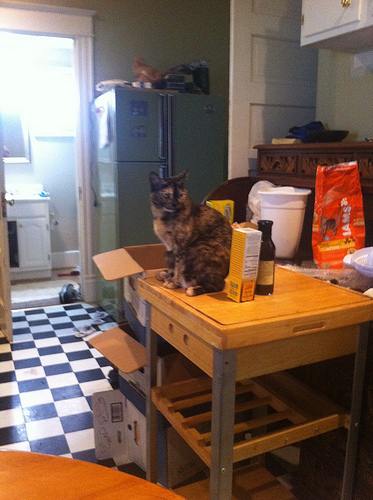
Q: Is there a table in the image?
A: Yes, there is a table.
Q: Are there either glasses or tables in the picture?
A: Yes, there is a table.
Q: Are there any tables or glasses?
A: Yes, there is a table.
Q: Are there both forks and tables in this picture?
A: No, there is a table but no forks.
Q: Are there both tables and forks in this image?
A: No, there is a table but no forks.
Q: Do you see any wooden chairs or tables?
A: Yes, there is a wood table.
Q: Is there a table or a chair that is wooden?
A: Yes, the table is wooden.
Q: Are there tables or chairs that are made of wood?
A: Yes, the table is made of wood.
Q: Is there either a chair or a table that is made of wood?
A: Yes, the table is made of wood.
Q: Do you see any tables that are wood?
A: Yes, there is a wood table.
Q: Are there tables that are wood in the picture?
A: Yes, there is a wood table.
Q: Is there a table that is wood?
A: Yes, there is a wood table.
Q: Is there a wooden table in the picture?
A: Yes, there is a wood table.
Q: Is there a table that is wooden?
A: Yes, there is a table that is wooden.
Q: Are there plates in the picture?
A: No, there are no plates.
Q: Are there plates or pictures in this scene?
A: No, there are no plates or pictures.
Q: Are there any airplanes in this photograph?
A: No, there are no airplanes.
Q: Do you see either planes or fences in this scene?
A: No, there are no planes or fences.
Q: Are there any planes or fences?
A: No, there are no planes or fences.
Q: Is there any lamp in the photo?
A: No, there are no lamps.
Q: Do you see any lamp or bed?
A: No, there are no lamps or beds.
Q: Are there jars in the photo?
A: No, there are no jars.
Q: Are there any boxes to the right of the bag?
A: No, the box is to the left of the bag.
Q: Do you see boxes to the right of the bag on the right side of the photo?
A: No, the box is to the left of the bag.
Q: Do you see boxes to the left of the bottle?
A: Yes, there is a box to the left of the bottle.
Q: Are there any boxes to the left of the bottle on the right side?
A: Yes, there is a box to the left of the bottle.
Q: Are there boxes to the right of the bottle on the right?
A: No, the box is to the left of the bottle.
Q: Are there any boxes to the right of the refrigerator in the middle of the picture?
A: Yes, there is a box to the right of the freezer.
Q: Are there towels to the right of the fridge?
A: No, there is a box to the right of the fridge.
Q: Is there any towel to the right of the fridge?
A: No, there is a box to the right of the fridge.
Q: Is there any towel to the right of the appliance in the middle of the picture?
A: No, there is a box to the right of the fridge.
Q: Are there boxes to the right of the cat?
A: Yes, there is a box to the right of the cat.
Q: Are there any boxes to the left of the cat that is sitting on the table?
A: No, the box is to the right of the cat.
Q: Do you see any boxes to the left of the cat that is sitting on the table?
A: No, the box is to the right of the cat.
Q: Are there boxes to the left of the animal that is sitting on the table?
A: No, the box is to the right of the cat.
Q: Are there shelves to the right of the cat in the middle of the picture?
A: No, there is a box to the right of the cat.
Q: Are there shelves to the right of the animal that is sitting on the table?
A: No, there is a box to the right of the cat.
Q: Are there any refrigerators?
A: Yes, there is a refrigerator.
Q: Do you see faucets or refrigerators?
A: Yes, there is a refrigerator.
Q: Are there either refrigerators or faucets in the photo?
A: Yes, there is a refrigerator.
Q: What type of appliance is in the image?
A: The appliance is a refrigerator.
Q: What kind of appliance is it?
A: The appliance is a refrigerator.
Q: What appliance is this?
A: This is a refrigerator.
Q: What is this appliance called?
A: This is a refrigerator.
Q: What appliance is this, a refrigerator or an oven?
A: This is a refrigerator.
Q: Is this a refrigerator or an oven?
A: This is a refrigerator.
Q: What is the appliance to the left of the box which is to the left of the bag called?
A: The appliance is a refrigerator.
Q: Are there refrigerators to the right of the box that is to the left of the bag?
A: No, the refrigerator is to the left of the box.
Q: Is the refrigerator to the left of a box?
A: Yes, the refrigerator is to the left of a box.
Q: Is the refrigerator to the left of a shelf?
A: No, the refrigerator is to the left of a box.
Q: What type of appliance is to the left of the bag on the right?
A: The appliance is a refrigerator.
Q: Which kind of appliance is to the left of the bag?
A: The appliance is a refrigerator.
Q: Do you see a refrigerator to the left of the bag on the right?
A: Yes, there is a refrigerator to the left of the bag.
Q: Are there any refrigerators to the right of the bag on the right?
A: No, the refrigerator is to the left of the bag.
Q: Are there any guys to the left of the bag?
A: No, there is a refrigerator to the left of the bag.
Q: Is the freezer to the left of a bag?
A: Yes, the freezer is to the left of a bag.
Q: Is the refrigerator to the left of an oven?
A: No, the refrigerator is to the left of a bag.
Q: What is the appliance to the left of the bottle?
A: The appliance is a refrigerator.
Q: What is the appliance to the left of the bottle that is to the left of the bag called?
A: The appliance is a refrigerator.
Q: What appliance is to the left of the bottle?
A: The appliance is a refrigerator.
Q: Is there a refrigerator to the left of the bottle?
A: Yes, there is a refrigerator to the left of the bottle.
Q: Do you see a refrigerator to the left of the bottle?
A: Yes, there is a refrigerator to the left of the bottle.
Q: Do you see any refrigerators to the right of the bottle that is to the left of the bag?
A: No, the refrigerator is to the left of the bottle.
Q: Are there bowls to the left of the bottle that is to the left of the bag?
A: No, there is a refrigerator to the left of the bottle.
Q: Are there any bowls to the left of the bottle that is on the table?
A: No, there is a refrigerator to the left of the bottle.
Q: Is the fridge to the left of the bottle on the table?
A: Yes, the fridge is to the left of the bottle.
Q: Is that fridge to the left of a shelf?
A: No, the fridge is to the left of the bottle.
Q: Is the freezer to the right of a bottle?
A: No, the freezer is to the left of a bottle.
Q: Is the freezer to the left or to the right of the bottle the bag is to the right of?
A: The freezer is to the left of the bottle.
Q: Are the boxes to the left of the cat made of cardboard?
A: Yes, the boxes are made of cardboard.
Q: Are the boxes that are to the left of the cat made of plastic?
A: No, the boxes are made of cardboard.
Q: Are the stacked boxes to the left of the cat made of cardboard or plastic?
A: The boxes are made of cardboard.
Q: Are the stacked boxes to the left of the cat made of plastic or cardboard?
A: The boxes are made of cardboard.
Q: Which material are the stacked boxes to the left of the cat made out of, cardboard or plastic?
A: The boxes are made of cardboard.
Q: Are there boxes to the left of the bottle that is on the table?
A: Yes, there are boxes to the left of the bottle.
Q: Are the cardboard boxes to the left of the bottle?
A: Yes, the boxes are to the left of the bottle.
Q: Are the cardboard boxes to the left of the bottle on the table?
A: Yes, the boxes are to the left of the bottle.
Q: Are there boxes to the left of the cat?
A: Yes, there are boxes to the left of the cat.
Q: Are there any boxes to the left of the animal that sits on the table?
A: Yes, there are boxes to the left of the cat.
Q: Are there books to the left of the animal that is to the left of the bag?
A: No, there are boxes to the left of the cat.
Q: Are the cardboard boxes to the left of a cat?
A: Yes, the boxes are to the left of a cat.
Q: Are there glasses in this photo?
A: No, there are no glasses.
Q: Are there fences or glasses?
A: No, there are no glasses or fences.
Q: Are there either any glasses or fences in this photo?
A: No, there are no glasses or fences.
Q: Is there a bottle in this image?
A: Yes, there is a bottle.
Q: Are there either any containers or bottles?
A: Yes, there is a bottle.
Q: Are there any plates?
A: No, there are no plates.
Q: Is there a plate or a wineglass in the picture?
A: No, there are no plates or wine glasses.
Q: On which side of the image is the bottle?
A: The bottle is on the right of the image.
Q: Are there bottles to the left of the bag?
A: Yes, there is a bottle to the left of the bag.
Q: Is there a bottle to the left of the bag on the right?
A: Yes, there is a bottle to the left of the bag.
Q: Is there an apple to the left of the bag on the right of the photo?
A: No, there is a bottle to the left of the bag.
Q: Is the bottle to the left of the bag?
A: Yes, the bottle is to the left of the bag.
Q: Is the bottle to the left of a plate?
A: No, the bottle is to the left of the bag.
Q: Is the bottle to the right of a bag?
A: No, the bottle is to the left of a bag.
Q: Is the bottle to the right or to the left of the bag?
A: The bottle is to the left of the bag.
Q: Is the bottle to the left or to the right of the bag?
A: The bottle is to the left of the bag.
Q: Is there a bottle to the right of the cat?
A: Yes, there is a bottle to the right of the cat.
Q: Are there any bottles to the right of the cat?
A: Yes, there is a bottle to the right of the cat.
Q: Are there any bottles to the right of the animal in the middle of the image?
A: Yes, there is a bottle to the right of the cat.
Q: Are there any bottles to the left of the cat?
A: No, the bottle is to the right of the cat.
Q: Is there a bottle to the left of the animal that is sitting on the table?
A: No, the bottle is to the right of the cat.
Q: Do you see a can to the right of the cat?
A: No, there is a bottle to the right of the cat.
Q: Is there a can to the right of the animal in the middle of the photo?
A: No, there is a bottle to the right of the cat.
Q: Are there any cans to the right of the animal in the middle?
A: No, there is a bottle to the right of the cat.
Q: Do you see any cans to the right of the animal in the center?
A: No, there is a bottle to the right of the cat.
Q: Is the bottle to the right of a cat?
A: Yes, the bottle is to the right of a cat.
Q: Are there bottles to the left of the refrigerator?
A: No, the bottle is to the right of the refrigerator.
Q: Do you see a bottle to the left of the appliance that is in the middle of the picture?
A: No, the bottle is to the right of the refrigerator.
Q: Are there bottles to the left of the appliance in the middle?
A: No, the bottle is to the right of the refrigerator.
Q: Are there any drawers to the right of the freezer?
A: No, there is a bottle to the right of the freezer.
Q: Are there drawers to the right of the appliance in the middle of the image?
A: No, there is a bottle to the right of the freezer.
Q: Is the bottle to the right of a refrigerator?
A: Yes, the bottle is to the right of a refrigerator.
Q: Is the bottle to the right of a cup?
A: No, the bottle is to the right of a refrigerator.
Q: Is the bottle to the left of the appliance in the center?
A: No, the bottle is to the right of the refrigerator.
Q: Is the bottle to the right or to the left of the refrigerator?
A: The bottle is to the right of the refrigerator.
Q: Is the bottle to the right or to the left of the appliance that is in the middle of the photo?
A: The bottle is to the right of the refrigerator.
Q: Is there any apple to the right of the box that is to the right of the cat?
A: No, there is a bottle to the right of the box.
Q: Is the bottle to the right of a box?
A: Yes, the bottle is to the right of a box.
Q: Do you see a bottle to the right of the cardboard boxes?
A: Yes, there is a bottle to the right of the boxes.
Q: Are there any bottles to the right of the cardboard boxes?
A: Yes, there is a bottle to the right of the boxes.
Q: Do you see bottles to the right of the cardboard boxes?
A: Yes, there is a bottle to the right of the boxes.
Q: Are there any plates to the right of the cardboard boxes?
A: No, there is a bottle to the right of the boxes.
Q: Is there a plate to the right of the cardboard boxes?
A: No, there is a bottle to the right of the boxes.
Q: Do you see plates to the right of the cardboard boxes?
A: No, there is a bottle to the right of the boxes.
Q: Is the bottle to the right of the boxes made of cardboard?
A: Yes, the bottle is to the right of the boxes.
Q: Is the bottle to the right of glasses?
A: No, the bottle is to the right of the boxes.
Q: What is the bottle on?
A: The bottle is on the table.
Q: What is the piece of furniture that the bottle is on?
A: The piece of furniture is a table.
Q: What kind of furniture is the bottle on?
A: The bottle is on the table.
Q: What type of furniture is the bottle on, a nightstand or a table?
A: The bottle is on a table.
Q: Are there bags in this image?
A: Yes, there is a bag.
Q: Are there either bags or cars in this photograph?
A: Yes, there is a bag.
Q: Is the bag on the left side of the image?
A: No, the bag is on the right of the image.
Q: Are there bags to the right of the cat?
A: Yes, there is a bag to the right of the cat.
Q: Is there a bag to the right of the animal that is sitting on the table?
A: Yes, there is a bag to the right of the cat.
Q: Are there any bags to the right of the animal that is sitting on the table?
A: Yes, there is a bag to the right of the cat.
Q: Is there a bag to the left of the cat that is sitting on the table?
A: No, the bag is to the right of the cat.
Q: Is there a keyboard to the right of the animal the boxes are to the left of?
A: No, there is a bag to the right of the cat.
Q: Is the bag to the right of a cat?
A: Yes, the bag is to the right of a cat.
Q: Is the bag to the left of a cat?
A: No, the bag is to the right of a cat.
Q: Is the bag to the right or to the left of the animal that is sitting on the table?
A: The bag is to the right of the cat.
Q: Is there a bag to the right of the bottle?
A: Yes, there is a bag to the right of the bottle.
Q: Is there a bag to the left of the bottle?
A: No, the bag is to the right of the bottle.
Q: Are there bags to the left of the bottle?
A: No, the bag is to the right of the bottle.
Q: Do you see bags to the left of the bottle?
A: No, the bag is to the right of the bottle.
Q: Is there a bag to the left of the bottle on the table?
A: No, the bag is to the right of the bottle.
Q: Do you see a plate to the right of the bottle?
A: No, there is a bag to the right of the bottle.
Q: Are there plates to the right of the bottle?
A: No, there is a bag to the right of the bottle.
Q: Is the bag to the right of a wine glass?
A: No, the bag is to the right of a bottle.